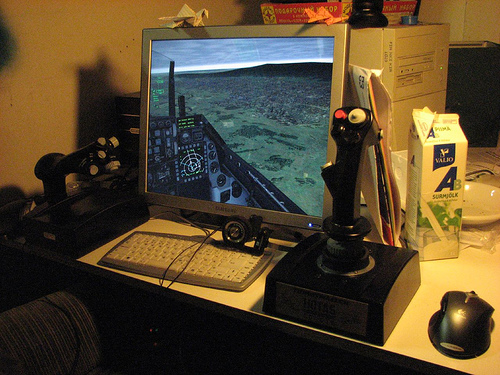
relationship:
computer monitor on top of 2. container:
[133, 25, 350, 234] [403, 105, 467, 260]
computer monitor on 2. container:
[133, 25, 350, 234] [403, 105, 467, 260]